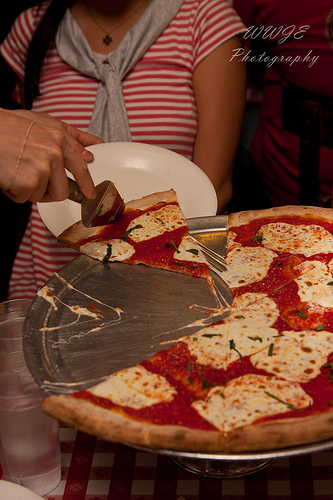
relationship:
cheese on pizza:
[231, 250, 264, 276] [56, 199, 212, 289]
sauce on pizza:
[144, 243, 169, 260] [56, 199, 212, 289]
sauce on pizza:
[147, 341, 235, 416] [40, 204, 332, 452]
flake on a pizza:
[195, 372, 213, 389] [42, 304, 222, 444]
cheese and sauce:
[258, 221, 332, 256] [228, 214, 332, 247]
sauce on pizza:
[228, 214, 332, 247] [54, 185, 332, 446]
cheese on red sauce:
[190, 372, 315, 430] [272, 249, 299, 326]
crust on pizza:
[40, 393, 151, 445] [40, 204, 332, 452]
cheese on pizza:
[190, 370, 315, 428] [54, 185, 332, 446]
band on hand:
[6, 113, 50, 202] [2, 115, 84, 188]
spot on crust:
[169, 422, 198, 450] [58, 391, 329, 461]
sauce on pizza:
[77, 200, 332, 436] [54, 185, 332, 446]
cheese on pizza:
[80, 204, 332, 431] [54, 185, 332, 446]